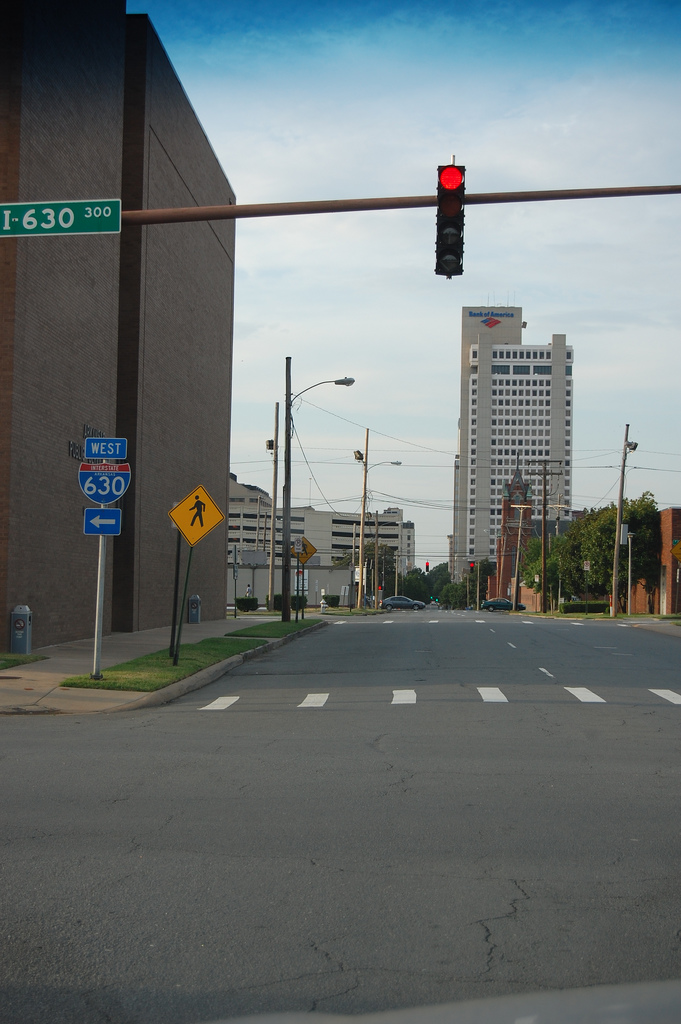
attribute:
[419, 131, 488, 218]
light — red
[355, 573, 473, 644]
car — grey 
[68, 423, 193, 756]
post — silver 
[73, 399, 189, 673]
post — green 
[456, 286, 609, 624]
building — grey 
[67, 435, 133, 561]
signs — street, couple 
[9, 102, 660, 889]
outside — scene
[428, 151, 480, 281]
light — red traffic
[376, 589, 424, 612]
car — blue 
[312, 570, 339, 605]
person — walking